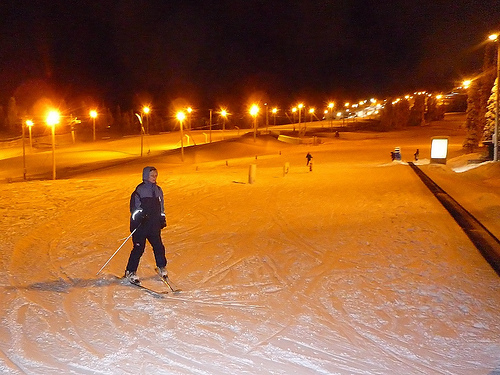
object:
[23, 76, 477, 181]
light row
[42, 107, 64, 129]
lights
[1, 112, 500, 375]
slope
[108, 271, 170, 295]
skis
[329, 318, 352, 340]
ski marks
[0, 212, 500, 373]
snow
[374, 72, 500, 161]
snow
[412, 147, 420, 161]
trees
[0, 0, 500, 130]
sky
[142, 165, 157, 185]
hood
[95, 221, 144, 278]
ski pole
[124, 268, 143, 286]
boots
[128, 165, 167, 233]
jacket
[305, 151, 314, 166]
person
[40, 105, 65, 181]
light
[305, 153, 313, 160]
dark jacket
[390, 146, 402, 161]
trash cans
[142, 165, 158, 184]
head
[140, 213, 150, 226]
gloves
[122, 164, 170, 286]
woman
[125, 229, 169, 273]
pants